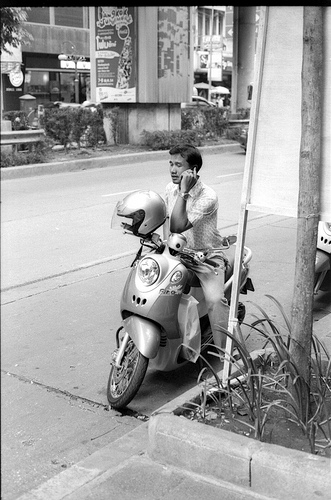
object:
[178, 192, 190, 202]
watch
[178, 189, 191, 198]
wrist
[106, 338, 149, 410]
tire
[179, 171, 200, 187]
cell phone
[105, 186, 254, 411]
scooter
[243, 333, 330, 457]
plants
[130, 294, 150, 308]
vent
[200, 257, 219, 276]
handle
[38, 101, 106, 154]
bush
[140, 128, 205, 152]
bush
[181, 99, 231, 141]
bush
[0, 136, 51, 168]
bush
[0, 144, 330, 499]
roadway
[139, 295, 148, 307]
holes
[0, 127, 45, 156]
fence barrier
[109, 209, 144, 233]
shield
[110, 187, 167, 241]
helmet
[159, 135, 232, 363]
guy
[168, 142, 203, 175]
hair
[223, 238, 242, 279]
backseat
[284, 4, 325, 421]
tree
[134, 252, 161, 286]
headlight